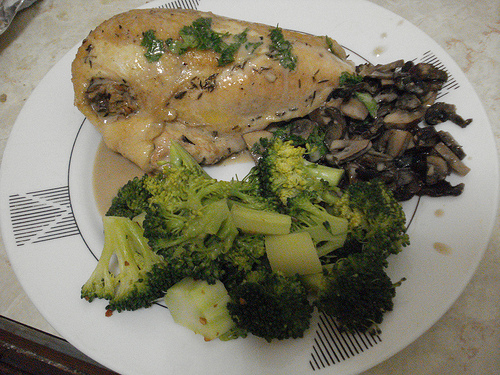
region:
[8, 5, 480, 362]
this is a plate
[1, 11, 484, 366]
the plate is round in shape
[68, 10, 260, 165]
this is meat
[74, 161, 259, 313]
this are broccolis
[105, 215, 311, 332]
the broccoli are green in color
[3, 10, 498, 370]
the plate is on the table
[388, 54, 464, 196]
this are sliced meat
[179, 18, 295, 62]
the meat has vegetables on it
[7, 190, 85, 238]
the plate has black stripes on it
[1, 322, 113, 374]
the table is wooden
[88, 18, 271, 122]
Delicious, moist chicken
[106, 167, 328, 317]
Beautiful, fresh, steamed brocolli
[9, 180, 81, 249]
Black lines and triangle design on a white plate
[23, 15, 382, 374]
An easy home cooked dinner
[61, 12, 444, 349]
A healthy dinner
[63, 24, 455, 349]
Make this healthy dinner in a snap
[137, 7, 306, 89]
Chicken cooked with herbs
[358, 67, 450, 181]
Delicious sauteed mushrooms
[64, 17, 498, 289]
If you are counting calories this is a great meal for you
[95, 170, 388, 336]
Broccoli can be steamed and added to the plate for a delicious side dish.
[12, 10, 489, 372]
a delicious meal on a plate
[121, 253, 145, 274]
red pepper flakes on broccoli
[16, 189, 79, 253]
a lined pattern on a plate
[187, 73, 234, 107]
black herbs on the chicken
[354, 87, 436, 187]
chopped fried mushrooms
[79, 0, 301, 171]
a grilled chicken breast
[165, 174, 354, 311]
steamed chopped broccoli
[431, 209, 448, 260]
oil dripping on the side of the plate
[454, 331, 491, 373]
a white granite counter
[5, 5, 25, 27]
the edge of a napkin on the table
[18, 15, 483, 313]
Food on a plate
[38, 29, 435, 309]
Food on a black and white plate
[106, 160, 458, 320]
Green food on a plate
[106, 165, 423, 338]
Broccoli on a plate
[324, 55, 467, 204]
Brown food on a plate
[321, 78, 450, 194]
Mushrooms on a plate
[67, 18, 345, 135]
Chicken on a plate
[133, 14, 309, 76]
Green seasoning on a piece of chicken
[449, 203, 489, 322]
The edge of a plate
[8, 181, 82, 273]
A black design on a white plate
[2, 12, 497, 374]
plate has food on it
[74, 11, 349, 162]
chicken breast is on plate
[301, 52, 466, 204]
mushrooms are on plate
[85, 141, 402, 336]
broccoli is on the plate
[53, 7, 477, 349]
the meal on the plate is very healthy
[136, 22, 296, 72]
fresh herbs are opn the chicken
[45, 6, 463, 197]
the mushroom is next to the chicken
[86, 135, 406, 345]
the broccoli is next to the mushrooms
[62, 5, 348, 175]
chicken is next to broccoli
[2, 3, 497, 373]
the plate is white with a black pattern